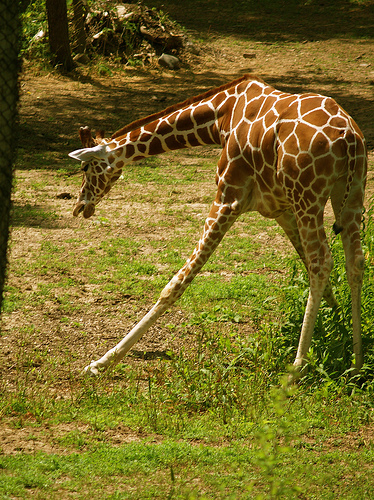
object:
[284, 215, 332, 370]
leg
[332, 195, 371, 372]
leg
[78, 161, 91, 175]
eyes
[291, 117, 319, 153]
spots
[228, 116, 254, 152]
spots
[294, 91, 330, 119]
spots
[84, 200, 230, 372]
front leg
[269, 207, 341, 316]
front leg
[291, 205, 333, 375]
back leg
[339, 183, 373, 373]
back leg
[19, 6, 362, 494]
park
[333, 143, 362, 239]
giraffe tail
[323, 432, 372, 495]
grass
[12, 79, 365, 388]
giraffe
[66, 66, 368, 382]
big giraffe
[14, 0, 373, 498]
field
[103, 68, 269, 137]
hair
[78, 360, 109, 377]
giraffe hoof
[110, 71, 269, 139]
mane